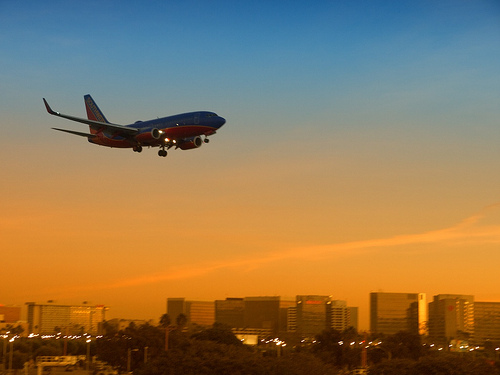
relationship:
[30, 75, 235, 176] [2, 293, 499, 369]
plane near city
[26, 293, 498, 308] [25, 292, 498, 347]
flat tops of tall buildings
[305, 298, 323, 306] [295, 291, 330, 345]
sign on top of building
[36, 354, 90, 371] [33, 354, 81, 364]
structure with railing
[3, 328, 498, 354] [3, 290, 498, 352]
lights along bottom of cityscape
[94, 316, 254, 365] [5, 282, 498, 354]
trees along cityscape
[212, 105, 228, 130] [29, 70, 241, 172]
nose of airplane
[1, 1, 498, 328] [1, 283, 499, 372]
sky above city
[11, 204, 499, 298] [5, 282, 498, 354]
cloud runs length of cityscape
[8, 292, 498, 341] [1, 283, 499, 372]
buildings in city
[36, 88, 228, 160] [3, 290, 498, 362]
plane flies above city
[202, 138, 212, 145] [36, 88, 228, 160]
wheel set on plane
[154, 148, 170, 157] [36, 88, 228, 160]
wheel set on plane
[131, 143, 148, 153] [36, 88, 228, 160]
wheel set on plane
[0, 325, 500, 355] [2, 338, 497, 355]
lights along roadway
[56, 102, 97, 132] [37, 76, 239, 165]
wing of airplane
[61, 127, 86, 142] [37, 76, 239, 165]
wing of airplane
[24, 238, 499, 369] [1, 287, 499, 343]
buildings along cityscape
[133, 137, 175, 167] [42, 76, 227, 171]
wheels on airplane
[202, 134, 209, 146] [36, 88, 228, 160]
front wheel on plane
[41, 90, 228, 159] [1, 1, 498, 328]
airplane in sky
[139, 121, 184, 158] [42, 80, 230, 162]
engine on airplane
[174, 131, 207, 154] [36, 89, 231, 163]
engine on airplane